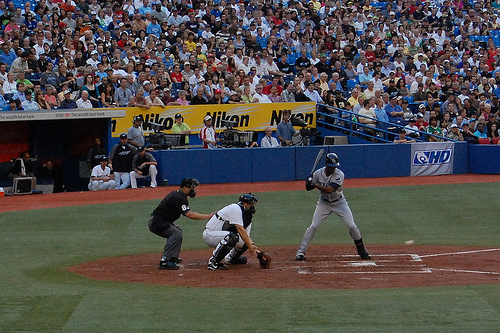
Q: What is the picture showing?
A: It is showing a field.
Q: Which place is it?
A: It is a field.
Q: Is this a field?
A: Yes, it is a field.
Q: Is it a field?
A: Yes, it is a field.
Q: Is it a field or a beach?
A: It is a field.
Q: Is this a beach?
A: No, it is a field.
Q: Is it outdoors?
A: Yes, it is outdoors.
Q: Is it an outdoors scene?
A: Yes, it is outdoors.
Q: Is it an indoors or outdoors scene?
A: It is outdoors.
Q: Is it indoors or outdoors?
A: It is outdoors.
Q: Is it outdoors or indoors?
A: It is outdoors.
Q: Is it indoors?
A: No, it is outdoors.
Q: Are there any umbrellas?
A: No, there are no umbrellas.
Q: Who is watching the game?
A: The people are watching the game.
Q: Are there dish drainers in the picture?
A: No, there are no dish drainers.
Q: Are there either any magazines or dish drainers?
A: No, there are no dish drainers or magazines.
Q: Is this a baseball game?
A: Yes, this is a baseball game.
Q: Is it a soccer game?
A: No, this is a baseball game.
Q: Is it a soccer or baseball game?
A: This is a baseball game.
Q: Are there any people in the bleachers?
A: Yes, there are people in the bleachers.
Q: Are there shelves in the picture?
A: No, there are no shelves.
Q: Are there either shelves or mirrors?
A: No, there are no shelves or mirrors.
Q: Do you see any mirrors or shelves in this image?
A: No, there are no shelves or mirrors.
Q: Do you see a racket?
A: No, there are no rackets.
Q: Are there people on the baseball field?
A: Yes, there is a person on the field.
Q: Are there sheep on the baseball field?
A: No, there is a person on the field.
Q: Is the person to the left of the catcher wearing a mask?
A: Yes, the person is wearing a mask.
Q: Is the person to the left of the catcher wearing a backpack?
A: No, the person is wearing a mask.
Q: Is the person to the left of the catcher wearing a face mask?
A: Yes, the person is wearing a face mask.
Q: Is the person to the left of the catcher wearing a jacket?
A: No, the person is wearing a face mask.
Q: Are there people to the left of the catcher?
A: Yes, there is a person to the left of the catcher.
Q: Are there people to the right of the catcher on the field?
A: No, the person is to the left of the catcher.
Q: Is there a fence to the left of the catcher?
A: No, there is a person to the left of the catcher.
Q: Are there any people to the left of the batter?
A: Yes, there is a person to the left of the batter.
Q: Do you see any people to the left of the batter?
A: Yes, there is a person to the left of the batter.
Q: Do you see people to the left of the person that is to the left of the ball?
A: Yes, there is a person to the left of the batter.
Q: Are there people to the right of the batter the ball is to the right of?
A: No, the person is to the left of the batter.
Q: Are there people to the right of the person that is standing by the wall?
A: No, the person is to the left of the batter.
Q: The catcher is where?
A: The catcher is on the field.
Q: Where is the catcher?
A: The catcher is on the field.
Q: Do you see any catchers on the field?
A: Yes, there is a catcher on the field.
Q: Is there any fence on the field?
A: No, there is a catcher on the field.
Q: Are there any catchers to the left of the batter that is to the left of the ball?
A: Yes, there is a catcher to the left of the batter.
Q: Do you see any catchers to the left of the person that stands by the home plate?
A: Yes, there is a catcher to the left of the batter.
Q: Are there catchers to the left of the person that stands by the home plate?
A: Yes, there is a catcher to the left of the batter.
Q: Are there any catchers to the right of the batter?
A: No, the catcher is to the left of the batter.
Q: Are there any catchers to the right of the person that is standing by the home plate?
A: No, the catcher is to the left of the batter.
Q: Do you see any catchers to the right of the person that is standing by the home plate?
A: No, the catcher is to the left of the batter.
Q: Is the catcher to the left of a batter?
A: Yes, the catcher is to the left of a batter.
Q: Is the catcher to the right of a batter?
A: No, the catcher is to the left of a batter.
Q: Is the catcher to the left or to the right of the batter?
A: The catcher is to the left of the batter.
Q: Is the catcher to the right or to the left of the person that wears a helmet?
A: The catcher is to the left of the batter.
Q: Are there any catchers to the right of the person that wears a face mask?
A: Yes, there is a catcher to the right of the person.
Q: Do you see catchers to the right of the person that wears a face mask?
A: Yes, there is a catcher to the right of the person.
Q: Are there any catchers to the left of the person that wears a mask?
A: No, the catcher is to the right of the person.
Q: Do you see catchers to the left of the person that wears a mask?
A: No, the catcher is to the right of the person.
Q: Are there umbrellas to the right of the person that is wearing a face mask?
A: No, there is a catcher to the right of the person.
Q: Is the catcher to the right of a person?
A: Yes, the catcher is to the right of a person.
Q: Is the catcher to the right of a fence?
A: No, the catcher is to the right of a person.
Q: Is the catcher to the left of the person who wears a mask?
A: No, the catcher is to the right of the person.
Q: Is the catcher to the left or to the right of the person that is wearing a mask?
A: The catcher is to the right of the person.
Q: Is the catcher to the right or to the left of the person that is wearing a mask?
A: The catcher is to the right of the person.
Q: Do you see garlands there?
A: No, there are no garlands.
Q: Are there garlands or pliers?
A: No, there are no garlands or pliers.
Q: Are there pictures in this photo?
A: No, there are no pictures.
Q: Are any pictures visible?
A: No, there are no pictures.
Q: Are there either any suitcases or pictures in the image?
A: No, there are no pictures or suitcases.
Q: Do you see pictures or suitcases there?
A: No, there are no pictures or suitcases.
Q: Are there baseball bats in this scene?
A: Yes, there is a baseball bat.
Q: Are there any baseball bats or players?
A: Yes, there is a baseball bat.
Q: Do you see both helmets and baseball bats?
A: Yes, there are both a baseball bat and a helmet.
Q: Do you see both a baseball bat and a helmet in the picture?
A: Yes, there are both a baseball bat and a helmet.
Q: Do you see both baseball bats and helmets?
A: Yes, there are both a baseball bat and a helmet.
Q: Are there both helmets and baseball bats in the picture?
A: Yes, there are both a baseball bat and a helmet.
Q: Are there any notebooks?
A: No, there are no notebooks.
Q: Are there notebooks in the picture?
A: No, there are no notebooks.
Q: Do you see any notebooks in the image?
A: No, there are no notebooks.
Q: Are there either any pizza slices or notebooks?
A: No, there are no notebooks or pizza slices.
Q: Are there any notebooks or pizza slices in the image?
A: No, there are no notebooks or pizza slices.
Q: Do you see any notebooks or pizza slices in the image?
A: No, there are no notebooks or pizza slices.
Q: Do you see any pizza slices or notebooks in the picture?
A: No, there are no notebooks or pizza slices.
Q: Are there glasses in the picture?
A: No, there are no glasses.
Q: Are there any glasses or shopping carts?
A: No, there are no glasses or shopping carts.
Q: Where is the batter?
A: The batter is on the field.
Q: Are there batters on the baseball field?
A: Yes, there is a batter on the field.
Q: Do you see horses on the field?
A: No, there is a batter on the field.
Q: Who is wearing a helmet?
A: The batter is wearing a helmet.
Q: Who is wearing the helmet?
A: The batter is wearing a helmet.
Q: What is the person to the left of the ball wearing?
A: The batter is wearing a helmet.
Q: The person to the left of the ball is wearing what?
A: The batter is wearing a helmet.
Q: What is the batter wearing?
A: The batter is wearing a helmet.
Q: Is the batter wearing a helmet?
A: Yes, the batter is wearing a helmet.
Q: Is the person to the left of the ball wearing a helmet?
A: Yes, the batter is wearing a helmet.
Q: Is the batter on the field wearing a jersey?
A: No, the batter is wearing a helmet.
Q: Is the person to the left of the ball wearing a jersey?
A: No, the batter is wearing a helmet.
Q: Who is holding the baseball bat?
A: The batter is holding the baseball bat.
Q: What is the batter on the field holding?
A: The batter is holding the baseball bat.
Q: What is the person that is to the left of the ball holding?
A: The batter is holding the baseball bat.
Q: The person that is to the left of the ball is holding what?
A: The batter is holding the baseball bat.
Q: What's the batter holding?
A: The batter is holding the baseball bat.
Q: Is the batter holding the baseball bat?
A: Yes, the batter is holding the baseball bat.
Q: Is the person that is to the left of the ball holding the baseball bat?
A: Yes, the batter is holding the baseball bat.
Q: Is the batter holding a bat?
A: No, the batter is holding the baseball bat.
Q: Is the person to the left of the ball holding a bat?
A: No, the batter is holding the baseball bat.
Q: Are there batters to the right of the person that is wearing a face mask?
A: Yes, there is a batter to the right of the person.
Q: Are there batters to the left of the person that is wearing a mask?
A: No, the batter is to the right of the person.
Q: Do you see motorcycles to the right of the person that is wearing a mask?
A: No, there is a batter to the right of the person.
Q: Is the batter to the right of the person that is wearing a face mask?
A: Yes, the batter is to the right of the person.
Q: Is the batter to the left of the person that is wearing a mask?
A: No, the batter is to the right of the person.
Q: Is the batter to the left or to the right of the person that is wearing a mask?
A: The batter is to the right of the person.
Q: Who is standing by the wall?
A: The batter is standing by the wall.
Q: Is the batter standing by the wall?
A: Yes, the batter is standing by the wall.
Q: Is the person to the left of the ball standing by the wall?
A: Yes, the batter is standing by the wall.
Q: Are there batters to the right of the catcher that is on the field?
A: Yes, there is a batter to the right of the catcher.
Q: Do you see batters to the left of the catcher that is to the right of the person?
A: No, the batter is to the right of the catcher.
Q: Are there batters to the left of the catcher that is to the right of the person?
A: No, the batter is to the right of the catcher.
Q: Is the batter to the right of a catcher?
A: Yes, the batter is to the right of a catcher.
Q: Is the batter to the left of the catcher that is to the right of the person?
A: No, the batter is to the right of the catcher.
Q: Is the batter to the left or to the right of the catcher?
A: The batter is to the right of the catcher.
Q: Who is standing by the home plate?
A: The batter is standing by the home plate.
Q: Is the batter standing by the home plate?
A: Yes, the batter is standing by the home plate.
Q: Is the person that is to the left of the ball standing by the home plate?
A: Yes, the batter is standing by the home plate.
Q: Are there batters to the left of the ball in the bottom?
A: Yes, there is a batter to the left of the ball.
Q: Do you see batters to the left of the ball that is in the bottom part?
A: Yes, there is a batter to the left of the ball.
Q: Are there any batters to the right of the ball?
A: No, the batter is to the left of the ball.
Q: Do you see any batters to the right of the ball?
A: No, the batter is to the left of the ball.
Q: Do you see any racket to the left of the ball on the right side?
A: No, there is a batter to the left of the ball.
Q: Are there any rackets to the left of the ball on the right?
A: No, there is a batter to the left of the ball.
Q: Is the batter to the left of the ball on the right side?
A: Yes, the batter is to the left of the ball.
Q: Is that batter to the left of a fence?
A: No, the batter is to the left of the ball.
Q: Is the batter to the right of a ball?
A: No, the batter is to the left of a ball.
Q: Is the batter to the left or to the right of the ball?
A: The batter is to the left of the ball.